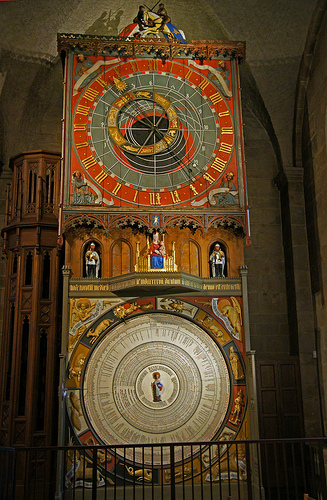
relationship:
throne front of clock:
[135, 232, 180, 273] [70, 57, 233, 207]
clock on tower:
[63, 49, 245, 215] [55, 0, 266, 495]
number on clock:
[130, 187, 142, 203] [63, 49, 245, 215]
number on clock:
[77, 153, 95, 169] [63, 49, 245, 215]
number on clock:
[74, 140, 87, 148] [53, 2, 263, 499]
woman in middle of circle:
[145, 230, 172, 283] [132, 362, 180, 408]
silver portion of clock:
[78, 310, 229, 470] [53, 2, 263, 499]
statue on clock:
[206, 241, 227, 275] [78, 60, 236, 202]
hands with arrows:
[110, 78, 209, 173] [122, 131, 176, 173]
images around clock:
[68, 296, 137, 352] [65, 46, 240, 210]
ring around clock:
[107, 75, 181, 164] [56, 211, 264, 490]